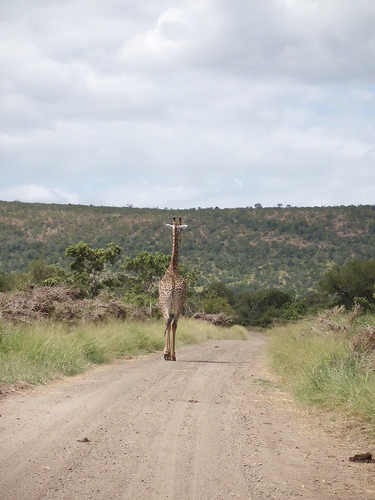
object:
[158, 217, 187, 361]
giraffe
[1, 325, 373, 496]
road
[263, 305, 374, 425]
field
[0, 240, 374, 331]
trees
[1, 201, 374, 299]
mountain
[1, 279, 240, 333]
hill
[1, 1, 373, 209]
sky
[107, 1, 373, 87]
cloud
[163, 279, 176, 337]
tail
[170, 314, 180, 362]
leg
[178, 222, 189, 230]
ear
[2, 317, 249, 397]
grass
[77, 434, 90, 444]
excrement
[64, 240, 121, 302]
trees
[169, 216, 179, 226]
horn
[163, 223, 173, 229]
ear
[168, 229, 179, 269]
neck